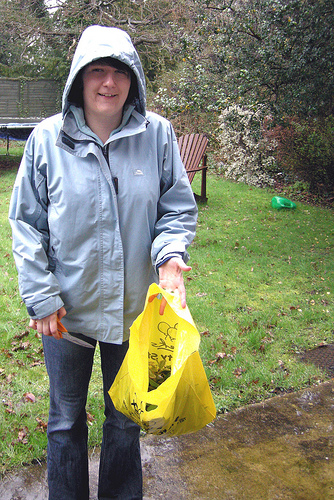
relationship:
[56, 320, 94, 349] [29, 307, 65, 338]
scissors in hand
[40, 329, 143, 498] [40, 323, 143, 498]
jeans on leg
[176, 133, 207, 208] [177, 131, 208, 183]
chair with slats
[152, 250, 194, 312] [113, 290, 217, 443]
hand holding bag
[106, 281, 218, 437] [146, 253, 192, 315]
bag in hand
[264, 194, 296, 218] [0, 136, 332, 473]
container on grass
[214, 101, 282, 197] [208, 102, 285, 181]
bush filled with flowers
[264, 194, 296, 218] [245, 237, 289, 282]
container in grass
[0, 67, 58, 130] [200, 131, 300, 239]
fence around yard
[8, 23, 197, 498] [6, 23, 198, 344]
woman wearing jacket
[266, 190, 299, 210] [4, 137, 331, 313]
cover on grass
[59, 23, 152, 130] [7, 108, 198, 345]
gray hood on jacket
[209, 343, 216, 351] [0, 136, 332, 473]
leaf on grass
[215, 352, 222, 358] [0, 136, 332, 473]
leaf on grass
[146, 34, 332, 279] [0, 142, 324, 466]
trees are on back of yard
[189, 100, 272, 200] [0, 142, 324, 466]
bushes are on back of yard